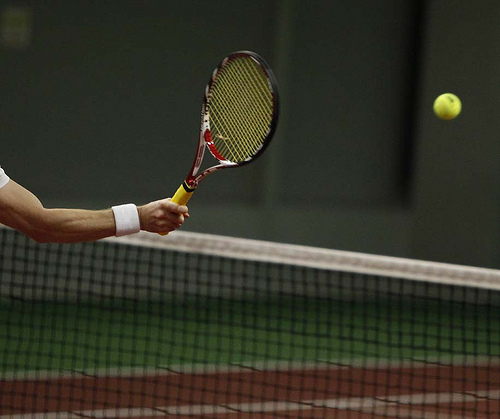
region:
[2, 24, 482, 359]
person hitting tennis ball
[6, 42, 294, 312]
this is an arm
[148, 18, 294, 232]
person holding tennis racket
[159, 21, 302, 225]
tennis racked is black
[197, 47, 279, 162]
yellow strings of racket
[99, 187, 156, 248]
a armband on wrtist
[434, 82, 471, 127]
neon green tennis ball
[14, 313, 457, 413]
white lines on court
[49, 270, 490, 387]
green trim on court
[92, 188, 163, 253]
wrist band is white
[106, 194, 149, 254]
wrist band is white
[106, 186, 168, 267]
wrist band is white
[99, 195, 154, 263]
wrist band is white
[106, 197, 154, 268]
wrist band is white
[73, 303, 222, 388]
the net is black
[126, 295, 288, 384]
the net is black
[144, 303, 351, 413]
the net is black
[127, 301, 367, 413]
the net is black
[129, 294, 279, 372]
the net is black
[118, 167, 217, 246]
the hand of a man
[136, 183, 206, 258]
the fingers of a man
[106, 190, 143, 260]
the wrist of a man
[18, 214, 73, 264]
the elbow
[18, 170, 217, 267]
the arm of a man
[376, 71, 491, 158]
a ball in the air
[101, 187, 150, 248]
a wrist band on a wrist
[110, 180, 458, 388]
a tennis net on a court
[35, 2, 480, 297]
a man playing tennis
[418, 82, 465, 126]
green tennis ball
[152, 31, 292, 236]
black and yellow tennis racket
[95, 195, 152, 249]
white wrist band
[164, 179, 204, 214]
yellow and black handle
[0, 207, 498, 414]
black tennis net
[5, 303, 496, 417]
green and red tennis court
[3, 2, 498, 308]
green wall on tennis court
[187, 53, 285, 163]
yellow net on tennis racket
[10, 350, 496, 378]
white lines on ground of tennis court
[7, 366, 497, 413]
red portion of tennis court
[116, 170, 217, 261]
the hand of a man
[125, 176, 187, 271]
the fingers of a man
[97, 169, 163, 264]
the wrist of a man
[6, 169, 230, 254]
the arm of a man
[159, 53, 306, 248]
a man holding a tennis racket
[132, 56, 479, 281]
a man hitting a ball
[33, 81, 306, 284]
a man playing tennis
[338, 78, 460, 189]
a green ball in the air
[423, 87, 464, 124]
yellow tennis ball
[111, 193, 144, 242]
white wristband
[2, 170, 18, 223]
sleeve of white shirt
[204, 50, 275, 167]
yellow strings on tennis racket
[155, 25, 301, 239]
black red and yellow tennis racket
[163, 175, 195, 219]
yellow handle on tennis racket